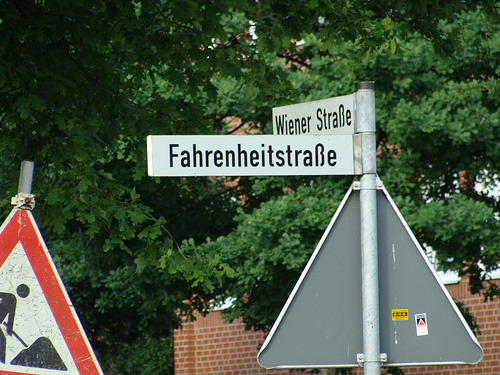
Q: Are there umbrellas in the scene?
A: No, there are no umbrellas.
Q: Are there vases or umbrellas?
A: No, there are no umbrellas or vases.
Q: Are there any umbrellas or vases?
A: No, there are no umbrellas or vases.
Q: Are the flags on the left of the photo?
A: Yes, the flags are on the left of the image.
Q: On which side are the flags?
A: The flags are on the left of the image.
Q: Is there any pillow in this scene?
A: No, there are no pillows.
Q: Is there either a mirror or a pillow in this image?
A: No, there are no pillows or mirrors.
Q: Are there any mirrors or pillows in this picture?
A: No, there are no pillows or mirrors.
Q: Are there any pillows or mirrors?
A: No, there are no pillows or mirrors.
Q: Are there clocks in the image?
A: No, there are no clocks.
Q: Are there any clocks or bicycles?
A: No, there are no clocks or bicycles.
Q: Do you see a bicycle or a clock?
A: No, there are no clocks or bicycles.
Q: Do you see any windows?
A: Yes, there is a window.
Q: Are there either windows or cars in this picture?
A: Yes, there is a window.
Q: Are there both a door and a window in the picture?
A: No, there is a window but no doors.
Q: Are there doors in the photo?
A: No, there are no doors.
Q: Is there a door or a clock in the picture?
A: No, there are no doors or clocks.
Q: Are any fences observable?
A: No, there are no fences.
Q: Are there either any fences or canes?
A: No, there are no fences or canes.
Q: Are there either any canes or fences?
A: No, there are no fences or canes.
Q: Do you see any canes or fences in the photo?
A: No, there are no fences or canes.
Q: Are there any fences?
A: No, there are no fences.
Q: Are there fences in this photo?
A: No, there are no fences.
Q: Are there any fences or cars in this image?
A: No, there are no fences or cars.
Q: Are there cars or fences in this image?
A: No, there are no fences or cars.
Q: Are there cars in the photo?
A: No, there are no cars.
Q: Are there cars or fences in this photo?
A: No, there are no cars or fences.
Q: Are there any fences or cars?
A: No, there are no cars or fences.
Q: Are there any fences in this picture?
A: No, there are no fences.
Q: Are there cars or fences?
A: No, there are no fences or cars.